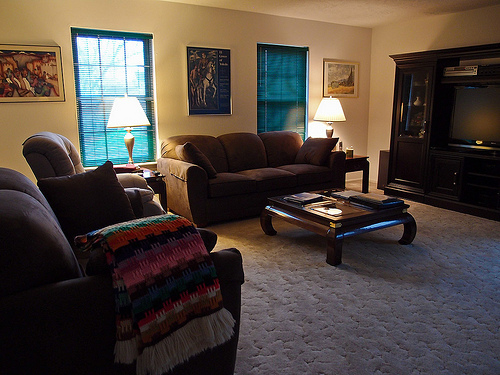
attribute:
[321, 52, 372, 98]
picture — framed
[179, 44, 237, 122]
artwork — framed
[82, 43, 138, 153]
mini blinds — blue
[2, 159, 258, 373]
blanket — afghan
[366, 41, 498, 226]
entertainment cabinet — wall sized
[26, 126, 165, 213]
recliner — beige 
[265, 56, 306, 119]
blinds — closed mini 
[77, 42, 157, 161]
window —  shades open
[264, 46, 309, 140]
window — shades shut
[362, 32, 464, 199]
stand — Large dark wood tv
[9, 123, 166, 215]
chair — Single person reclining sofa 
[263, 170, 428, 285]
coffee table — wooden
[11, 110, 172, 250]
recliner chair — leather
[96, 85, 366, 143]
lampshades — white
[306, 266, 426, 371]
carpet — light brown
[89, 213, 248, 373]
afghan — colorful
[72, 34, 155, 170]
blinds — blue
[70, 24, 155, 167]
blinds — horizontal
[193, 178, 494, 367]
floor — carpeted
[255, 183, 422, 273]
table — large, wooden, brown, square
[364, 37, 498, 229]
cabinet — large, tall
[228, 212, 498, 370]
carpet — large, open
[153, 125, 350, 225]
couch — brown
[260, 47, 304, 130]
blinds — blue, mini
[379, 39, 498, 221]
entertainment center — large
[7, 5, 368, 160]
wall — white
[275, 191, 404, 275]
coffee table — square, stacked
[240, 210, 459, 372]
carpet — beige, hi-low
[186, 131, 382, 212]
couch — brown, leather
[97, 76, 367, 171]
lamps — matching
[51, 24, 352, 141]
artwork — framed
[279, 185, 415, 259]
table — dark, wood, square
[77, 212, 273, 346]
blanket — hanging, quilted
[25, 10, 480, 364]
living room — inside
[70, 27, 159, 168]
window — large, tall, open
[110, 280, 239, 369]
fringe — grey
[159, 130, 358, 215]
couch — large, brown, cloth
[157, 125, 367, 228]
sofa — long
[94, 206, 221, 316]
blanket — large, multi colored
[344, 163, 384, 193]
table — small, short, wooden, end table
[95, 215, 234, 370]
blanket — folded